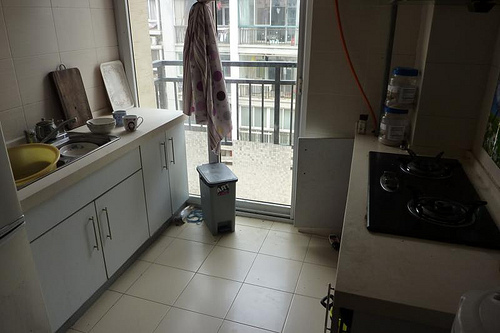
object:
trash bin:
[196, 161, 238, 236]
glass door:
[123, 0, 301, 212]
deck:
[149, 130, 293, 205]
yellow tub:
[6, 143, 59, 187]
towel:
[180, 0, 233, 156]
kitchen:
[0, 0, 500, 333]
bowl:
[86, 117, 115, 135]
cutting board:
[49, 64, 95, 130]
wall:
[0, 0, 120, 148]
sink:
[9, 131, 120, 193]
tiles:
[62, 217, 338, 333]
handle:
[101, 207, 112, 240]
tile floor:
[59, 208, 343, 333]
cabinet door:
[293, 136, 355, 228]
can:
[196, 162, 239, 237]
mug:
[122, 115, 144, 132]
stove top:
[365, 150, 500, 249]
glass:
[145, 0, 300, 209]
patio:
[231, 138, 295, 205]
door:
[144, 0, 299, 221]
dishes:
[59, 142, 100, 158]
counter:
[0, 107, 190, 333]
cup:
[112, 109, 127, 126]